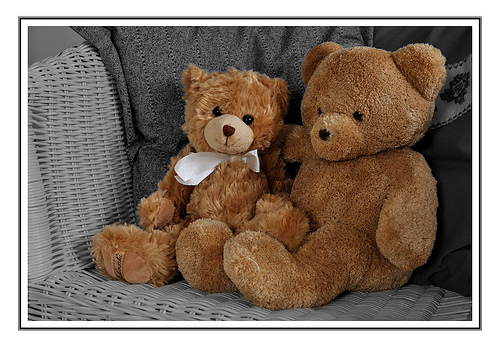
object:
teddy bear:
[91, 65, 294, 293]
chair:
[28, 27, 471, 321]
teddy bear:
[174, 42, 448, 308]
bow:
[173, 149, 261, 185]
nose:
[318, 129, 330, 142]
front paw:
[155, 199, 175, 229]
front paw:
[377, 232, 428, 272]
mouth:
[215, 138, 239, 147]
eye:
[212, 105, 223, 117]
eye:
[242, 114, 254, 124]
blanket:
[70, 25, 372, 228]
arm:
[158, 146, 195, 208]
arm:
[277, 123, 308, 163]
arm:
[378, 151, 437, 238]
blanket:
[373, 26, 471, 297]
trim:
[426, 53, 470, 130]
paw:
[91, 224, 168, 285]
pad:
[100, 245, 150, 284]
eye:
[317, 107, 322, 115]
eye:
[352, 110, 364, 120]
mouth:
[318, 146, 353, 161]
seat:
[36, 264, 471, 321]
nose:
[223, 125, 236, 138]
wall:
[29, 26, 97, 65]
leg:
[174, 218, 239, 294]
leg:
[221, 227, 373, 311]